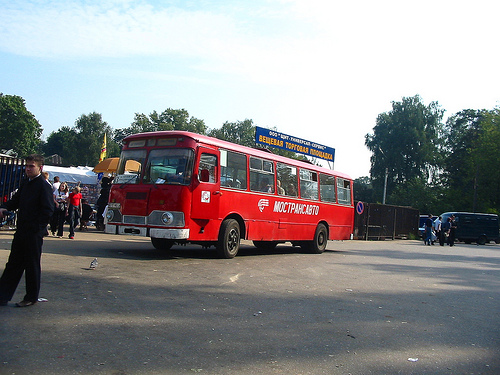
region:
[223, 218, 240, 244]
Black tire near front of bus.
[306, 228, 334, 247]
Black tire near back of bus.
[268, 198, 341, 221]
White letters on side of bus.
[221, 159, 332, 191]
Large windows on side of bus.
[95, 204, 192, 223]
Lights on front of bus.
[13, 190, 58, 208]
Person wearing black coat.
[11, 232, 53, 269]
Person wearing black pants.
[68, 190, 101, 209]
Person wearing red shirt.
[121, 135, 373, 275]
Large red bus on pavement.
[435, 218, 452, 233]
Person wearing white shirt.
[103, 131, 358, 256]
a red bus parked in a parking lot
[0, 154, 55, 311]
a man wearing black in a parking lot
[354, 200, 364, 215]
a red and blue road sign on a fence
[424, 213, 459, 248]
people walking close to a black van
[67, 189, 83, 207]
person wearing a red shirt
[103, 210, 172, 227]
round head lights of a bus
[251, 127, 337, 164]
a blue banner with white and yellow writing on it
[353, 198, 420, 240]
a rusted metal fence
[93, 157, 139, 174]
a light brown canopy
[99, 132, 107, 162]
a flag on a pole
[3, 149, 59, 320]
a man standing on pavement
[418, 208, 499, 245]
a group of people stand by a van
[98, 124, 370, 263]
a large red bus with a blue sign on top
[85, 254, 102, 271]
a bird on the ground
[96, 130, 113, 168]
a yellow flag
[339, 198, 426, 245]
a large metal dumpster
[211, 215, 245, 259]
the tire of a bus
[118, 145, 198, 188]
the front windshield of a bus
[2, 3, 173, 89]
a partly cloudy sky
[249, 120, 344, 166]
a large blue sign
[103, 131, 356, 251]
red bus in lot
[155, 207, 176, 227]
left headlight on bus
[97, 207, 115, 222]
right headlight on bus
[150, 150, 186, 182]
window on the bus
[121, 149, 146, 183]
right window on the bus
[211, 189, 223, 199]
handle on the door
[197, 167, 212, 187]
sideview mirror on the bus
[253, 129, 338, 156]
blue sign in air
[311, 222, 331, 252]
rear tire on bus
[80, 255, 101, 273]
bird on the ground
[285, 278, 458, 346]
grey pavement in parking lot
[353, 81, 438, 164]
tree covered in green leaves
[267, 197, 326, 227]
writing on side of red bus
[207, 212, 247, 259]
large black tire on bus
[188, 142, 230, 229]
red metal door on side of bus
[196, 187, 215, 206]
sign on side of metal bus door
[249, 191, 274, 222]
design on side of red bus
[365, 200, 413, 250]
row of black metal fencing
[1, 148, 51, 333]
man in black clothing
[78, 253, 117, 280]
small grey bird standing on pavement